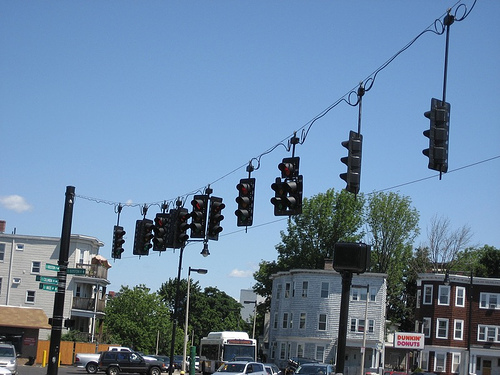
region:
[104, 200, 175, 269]
signal lights hanging above street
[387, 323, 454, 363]
white sign with orange and pink writing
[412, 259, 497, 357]
brick building with many windows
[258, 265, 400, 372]
gray corner building with many windows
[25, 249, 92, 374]
green and white street signs on black pole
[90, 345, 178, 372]
black SUV parked in parking lot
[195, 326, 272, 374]
city bus driving on street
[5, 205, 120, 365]
multi level building on main street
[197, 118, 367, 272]
signal lights hanging above street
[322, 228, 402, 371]
cross walk signal light on black metal pole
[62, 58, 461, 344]
string of black traffic lights above intersection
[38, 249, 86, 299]
Green signs on pole at intersection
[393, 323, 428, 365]
dunkin donuts sign in front of building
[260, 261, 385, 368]
light blue building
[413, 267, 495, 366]
red brick building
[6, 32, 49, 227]
blue sky with few clouds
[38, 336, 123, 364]
light colored wooden fence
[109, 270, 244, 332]
tree tops are in the background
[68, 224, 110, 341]
three balconies on the building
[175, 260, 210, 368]
street light at intersection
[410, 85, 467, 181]
Traffic light facing with backside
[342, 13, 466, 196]
Two traffic lights facing the other way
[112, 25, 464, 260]
Nine traffic lights facing different directions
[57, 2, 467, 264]
Long pole with traffic lights resting below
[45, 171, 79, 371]
Tall black pole on street end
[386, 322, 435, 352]
Dunking Donuts sign between buildings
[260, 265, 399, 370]
White building on street corner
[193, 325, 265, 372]
Bus heading forward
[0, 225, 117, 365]
White building with balconies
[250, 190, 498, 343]
Green tall trees behind two buildings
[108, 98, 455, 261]
string of traffic lights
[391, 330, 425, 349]
Dunkin' Donuts sign in front of building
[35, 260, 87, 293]
four green street signs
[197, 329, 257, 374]
city bus at traffic light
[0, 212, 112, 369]
tan building behind street signs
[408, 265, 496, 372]
brown and white building behind donut sign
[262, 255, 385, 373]
large grey house with many windows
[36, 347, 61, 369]
bright yellow guard rails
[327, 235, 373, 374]
black electric cross walk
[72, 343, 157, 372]
silver truck behind black suv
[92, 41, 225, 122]
crystal clear blue skies overhead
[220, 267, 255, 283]
small soft white cloud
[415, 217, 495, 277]
bare tall tree in the distance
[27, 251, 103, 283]
green and white sign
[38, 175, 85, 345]
large black post on sidewalk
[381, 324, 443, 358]
large white sign on building front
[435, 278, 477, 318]
white window in brown building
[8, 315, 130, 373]
orange fence on side wal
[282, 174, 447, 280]
large cluster of green trees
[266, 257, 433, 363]
large gray building on side of road